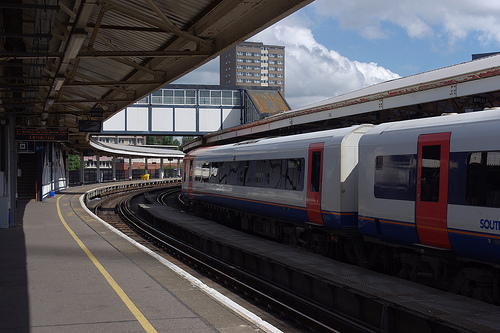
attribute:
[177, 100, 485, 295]
passenger train — blue, white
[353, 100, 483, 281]
train car — full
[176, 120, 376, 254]
train car — full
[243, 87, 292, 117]
roof — rusted, angled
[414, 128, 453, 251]
door — red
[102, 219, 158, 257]
edge — white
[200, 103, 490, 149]
roof — white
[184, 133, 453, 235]
door — red, blue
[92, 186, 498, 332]
track — steel, gray, metal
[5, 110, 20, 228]
pole — gray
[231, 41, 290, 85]
building — brown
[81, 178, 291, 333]
line — white, yellow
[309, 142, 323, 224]
stripe — red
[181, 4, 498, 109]
sky — clear, fluffy